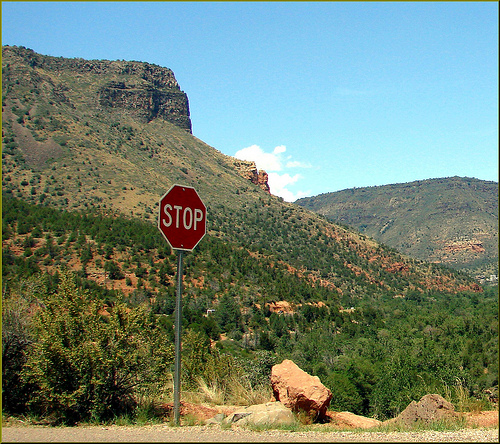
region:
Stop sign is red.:
[146, 182, 300, 377]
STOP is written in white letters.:
[152, 181, 222, 279]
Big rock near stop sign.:
[248, 325, 372, 442]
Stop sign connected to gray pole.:
[123, 257, 241, 383]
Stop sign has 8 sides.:
[151, 214, 221, 301]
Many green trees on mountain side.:
[215, 150, 463, 387]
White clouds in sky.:
[226, 129, 321, 226]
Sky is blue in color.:
[316, 123, 463, 169]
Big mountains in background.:
[246, 161, 471, 346]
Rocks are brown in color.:
[251, 352, 405, 438]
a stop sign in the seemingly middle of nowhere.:
[152, 178, 215, 429]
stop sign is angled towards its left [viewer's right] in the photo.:
[151, 180, 216, 426]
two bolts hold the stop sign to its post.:
[175, 185, 185, 250]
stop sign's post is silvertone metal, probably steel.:
[166, 245, 181, 427]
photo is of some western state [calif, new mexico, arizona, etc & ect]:
[1, 1, 498, 442]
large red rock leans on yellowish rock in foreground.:
[220, 352, 332, 427]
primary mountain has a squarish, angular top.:
[0, 36, 195, 136]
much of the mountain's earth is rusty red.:
[1, 212, 481, 327]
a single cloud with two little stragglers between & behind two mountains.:
[230, 135, 316, 207]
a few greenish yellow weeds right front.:
[430, 371, 498, 425]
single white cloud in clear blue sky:
[220, 128, 317, 216]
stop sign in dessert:
[144, 167, 229, 438]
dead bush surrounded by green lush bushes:
[3, 272, 46, 389]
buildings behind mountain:
[473, 268, 499, 298]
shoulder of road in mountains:
[7, 424, 487, 442]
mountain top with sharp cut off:
[7, 40, 245, 160]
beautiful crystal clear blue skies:
[8, 7, 490, 47]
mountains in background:
[36, 50, 498, 227]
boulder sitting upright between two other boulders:
[259, 340, 351, 438]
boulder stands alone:
[371, 386, 493, 440]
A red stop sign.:
[150, 176, 215, 254]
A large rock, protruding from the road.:
[266, 351, 335, 427]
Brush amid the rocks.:
[258, 311, 479, 435]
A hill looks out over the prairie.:
[0, 49, 191, 124]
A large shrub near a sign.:
[18, 266, 128, 430]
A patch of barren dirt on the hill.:
[0, 106, 67, 181]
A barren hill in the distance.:
[295, 168, 499, 270]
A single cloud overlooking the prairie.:
[227, 133, 305, 183]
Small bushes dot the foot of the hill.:
[2, 167, 153, 280]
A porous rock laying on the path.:
[388, 393, 458, 428]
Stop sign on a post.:
[156, 180, 209, 428]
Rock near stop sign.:
[265, 355, 334, 424]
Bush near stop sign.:
[23, 272, 166, 421]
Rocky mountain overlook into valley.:
[37, 42, 201, 154]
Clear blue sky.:
[172, 14, 484, 99]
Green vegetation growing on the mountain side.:
[9, 188, 479, 333]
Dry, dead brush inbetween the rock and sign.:
[188, 365, 278, 418]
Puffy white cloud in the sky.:
[221, 132, 312, 209]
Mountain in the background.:
[285, 175, 499, 264]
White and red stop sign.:
[151, 172, 220, 267]